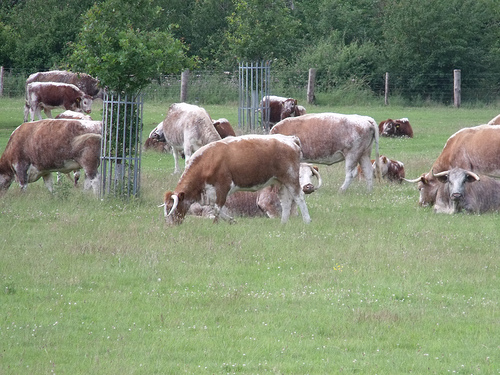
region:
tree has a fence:
[88, 14, 138, 201]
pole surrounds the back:
[444, 64, 465, 109]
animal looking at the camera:
[439, 167, 498, 230]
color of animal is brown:
[150, 139, 332, 233]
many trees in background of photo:
[246, 1, 493, 56]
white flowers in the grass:
[193, 275, 368, 333]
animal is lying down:
[355, 111, 421, 138]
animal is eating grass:
[165, 130, 357, 230]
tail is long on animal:
[363, 101, 386, 192]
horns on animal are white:
[159, 191, 187, 214]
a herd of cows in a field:
[11, 18, 482, 333]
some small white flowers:
[273, 281, 367, 308]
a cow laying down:
[427, 162, 499, 227]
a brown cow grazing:
[158, 134, 353, 251]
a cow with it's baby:
[13, 48, 141, 126]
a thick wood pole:
[447, 63, 468, 115]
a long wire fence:
[120, 67, 483, 117]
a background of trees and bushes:
[0, 0, 483, 130]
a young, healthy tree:
[73, 21, 200, 216]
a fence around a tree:
[87, 78, 162, 218]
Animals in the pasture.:
[0, 53, 498, 226]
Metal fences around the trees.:
[93, 58, 289, 215]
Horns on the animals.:
[153, 164, 498, 219]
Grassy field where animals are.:
[3, 97, 493, 371]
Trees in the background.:
[2, 2, 493, 115]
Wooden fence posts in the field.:
[169, 63, 466, 103]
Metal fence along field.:
[138, 64, 498, 109]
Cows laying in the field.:
[143, 96, 413, 222]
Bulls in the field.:
[151, 92, 496, 235]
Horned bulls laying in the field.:
[395, 161, 496, 221]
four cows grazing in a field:
[3, 106, 392, 234]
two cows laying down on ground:
[408, 160, 495, 225]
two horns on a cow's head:
[418, 165, 480, 205]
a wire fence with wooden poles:
[302, 60, 472, 106]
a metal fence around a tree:
[85, 61, 152, 206]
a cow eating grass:
[151, 132, 299, 237]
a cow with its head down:
[148, 130, 308, 232]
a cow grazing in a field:
[148, 128, 325, 230]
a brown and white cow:
[156, 125, 312, 240]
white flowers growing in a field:
[203, 286, 380, 323]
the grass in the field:
[82, 256, 395, 355]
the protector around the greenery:
[99, 89, 141, 201]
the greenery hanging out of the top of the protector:
[77, 28, 177, 95]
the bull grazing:
[157, 135, 307, 225]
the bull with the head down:
[157, 134, 305, 228]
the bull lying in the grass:
[427, 167, 498, 217]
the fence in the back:
[300, 65, 496, 107]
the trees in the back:
[178, 1, 494, 63]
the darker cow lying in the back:
[378, 118, 412, 138]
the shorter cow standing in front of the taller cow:
[27, 83, 92, 117]